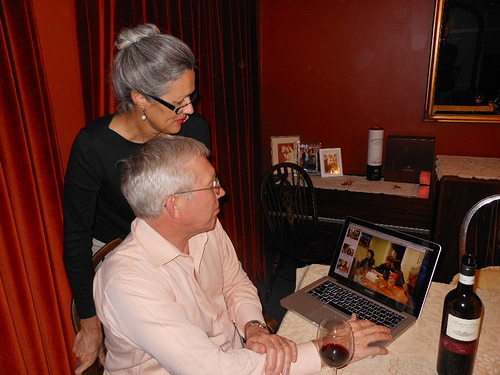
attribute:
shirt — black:
[94, 121, 239, 338]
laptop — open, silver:
[282, 219, 448, 348]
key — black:
[345, 292, 358, 306]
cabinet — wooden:
[267, 172, 434, 272]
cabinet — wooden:
[271, 163, 468, 261]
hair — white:
[119, 133, 202, 204]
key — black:
[319, 297, 404, 353]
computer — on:
[276, 216, 443, 350]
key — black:
[349, 298, 354, 306]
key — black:
[314, 290, 324, 298]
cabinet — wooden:
[262, 170, 434, 255]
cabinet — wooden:
[262, 175, 450, 280]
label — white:
[442, 316, 484, 343]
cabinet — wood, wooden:
[266, 170, 436, 322]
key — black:
[349, 289, 354, 297]